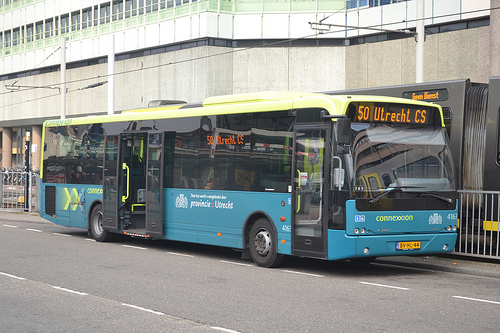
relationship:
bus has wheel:
[35, 82, 469, 269] [238, 209, 287, 270]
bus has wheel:
[35, 82, 469, 269] [81, 195, 117, 245]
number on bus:
[352, 101, 373, 125] [35, 82, 469, 269]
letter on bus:
[228, 199, 238, 212] [35, 82, 469, 269]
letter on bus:
[373, 215, 383, 225] [35, 82, 469, 269]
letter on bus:
[187, 199, 197, 212] [35, 82, 469, 269]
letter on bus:
[210, 199, 223, 211] [35, 82, 469, 269]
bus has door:
[35, 82, 469, 269] [119, 134, 154, 239]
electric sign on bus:
[350, 102, 443, 130] [35, 82, 469, 269]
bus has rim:
[35, 82, 469, 269] [251, 226, 274, 259]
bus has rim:
[35, 82, 469, 269] [90, 209, 106, 239]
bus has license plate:
[35, 82, 469, 269] [391, 237, 426, 256]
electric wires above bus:
[6, 7, 499, 115] [35, 82, 469, 269]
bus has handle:
[35, 82, 469, 269] [119, 160, 135, 206]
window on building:
[79, 6, 95, 34] [0, 1, 499, 129]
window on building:
[22, 21, 39, 47] [0, 1, 499, 129]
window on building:
[54, 12, 73, 39] [0, 1, 499, 129]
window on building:
[123, 1, 141, 20] [0, 1, 499, 129]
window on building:
[97, 1, 114, 31] [0, 1, 499, 129]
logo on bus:
[423, 209, 447, 230] [35, 82, 469, 269]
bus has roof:
[35, 82, 469, 269] [38, 92, 449, 134]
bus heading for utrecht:
[35, 82, 469, 269] [373, 102, 413, 128]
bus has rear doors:
[35, 82, 469, 269] [99, 128, 173, 241]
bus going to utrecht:
[35, 82, 469, 269] [373, 102, 413, 128]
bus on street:
[35, 82, 469, 269] [0, 211, 499, 331]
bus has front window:
[35, 82, 469, 269] [350, 122, 460, 211]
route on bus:
[371, 103, 430, 127] [35, 82, 469, 269]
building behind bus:
[0, 1, 499, 129] [35, 82, 469, 269]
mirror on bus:
[328, 154, 347, 198] [35, 82, 469, 269]